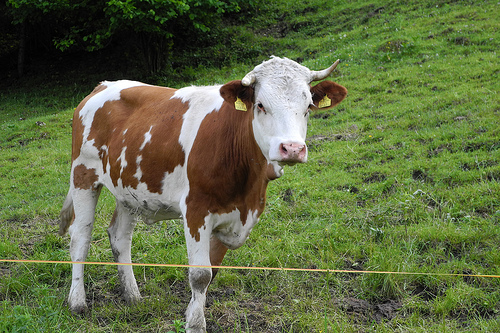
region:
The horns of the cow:
[237, 56, 342, 88]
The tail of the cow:
[51, 114, 79, 236]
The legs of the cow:
[54, 158, 239, 330]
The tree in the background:
[1, 0, 253, 90]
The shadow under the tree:
[2, 28, 177, 109]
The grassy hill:
[2, 3, 499, 328]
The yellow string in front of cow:
[0, 252, 499, 284]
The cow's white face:
[248, 51, 318, 176]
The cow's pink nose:
[274, 137, 314, 172]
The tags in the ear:
[234, 88, 334, 118]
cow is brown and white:
[88, 73, 334, 318]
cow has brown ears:
[207, 73, 254, 106]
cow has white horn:
[313, 60, 348, 92]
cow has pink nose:
[280, 136, 322, 180]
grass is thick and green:
[274, 60, 459, 277]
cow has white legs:
[155, 220, 220, 332]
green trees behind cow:
[3, 3, 228, 73]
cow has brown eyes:
[248, 88, 270, 119]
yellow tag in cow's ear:
[324, 97, 340, 117]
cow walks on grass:
[73, 67, 376, 325]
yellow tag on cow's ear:
[215, 80, 251, 116]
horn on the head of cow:
[307, 54, 347, 82]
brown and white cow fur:
[151, 101, 226, 190]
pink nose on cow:
[275, 134, 307, 163]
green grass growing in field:
[369, 151, 470, 260]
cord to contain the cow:
[0, 235, 490, 295]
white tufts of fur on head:
[267, 65, 302, 100]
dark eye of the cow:
[256, 97, 267, 114]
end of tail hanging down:
[53, 194, 76, 235]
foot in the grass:
[60, 282, 99, 326]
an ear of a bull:
[310, 80, 350, 108]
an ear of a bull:
[217, 78, 256, 112]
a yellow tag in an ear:
[232, 96, 249, 116]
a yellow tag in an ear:
[316, 91, 334, 111]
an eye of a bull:
[256, 96, 269, 113]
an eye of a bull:
[306, 100, 318, 112]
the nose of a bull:
[271, 139, 312, 167]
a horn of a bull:
[309, 60, 350, 81]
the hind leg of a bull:
[56, 165, 105, 312]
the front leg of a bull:
[181, 221, 220, 331]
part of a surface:
[406, 190, 422, 207]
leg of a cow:
[193, 245, 206, 302]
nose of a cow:
[291, 151, 299, 161]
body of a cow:
[153, 86, 160, 112]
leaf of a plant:
[168, 23, 202, 58]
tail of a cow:
[63, 190, 68, 207]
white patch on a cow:
[172, 148, 194, 166]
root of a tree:
[154, 60, 166, 63]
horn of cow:
[322, 68, 337, 79]